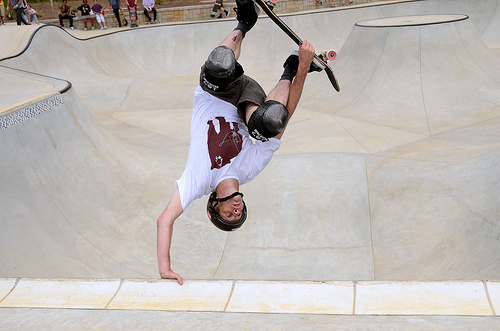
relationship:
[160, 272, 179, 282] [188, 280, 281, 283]
hand grabbing curb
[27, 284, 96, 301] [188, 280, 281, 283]
concrete tile in curb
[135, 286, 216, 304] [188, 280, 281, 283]
concrete tile in curb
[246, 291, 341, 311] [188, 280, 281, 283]
concrete tile in curb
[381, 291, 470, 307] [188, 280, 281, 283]
concrete tile on curb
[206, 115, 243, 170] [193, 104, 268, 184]
bear on shirt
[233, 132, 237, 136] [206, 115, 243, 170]
muzzle on bear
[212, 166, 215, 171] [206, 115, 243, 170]
ear on bear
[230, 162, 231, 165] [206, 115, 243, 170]
ear on bear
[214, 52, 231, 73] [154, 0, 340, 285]
kneepad on skateboarder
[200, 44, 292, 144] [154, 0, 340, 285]
kneepads on skateboarder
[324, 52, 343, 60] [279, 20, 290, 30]
wheel on skateboard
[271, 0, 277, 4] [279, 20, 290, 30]
wheel on skateboard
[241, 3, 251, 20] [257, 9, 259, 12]
sneaker on rubber sole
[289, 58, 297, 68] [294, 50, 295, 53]
sneaker on rubber sole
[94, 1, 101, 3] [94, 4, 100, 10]
person wearing shirt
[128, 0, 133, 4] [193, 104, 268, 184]
person wearing shirt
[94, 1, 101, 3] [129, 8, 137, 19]
person with skateboard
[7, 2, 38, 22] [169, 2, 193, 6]
people in background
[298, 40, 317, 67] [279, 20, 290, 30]
hand on skateboard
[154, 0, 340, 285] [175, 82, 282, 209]
skateboarder wearing shirt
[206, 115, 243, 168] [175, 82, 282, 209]
bear on shirt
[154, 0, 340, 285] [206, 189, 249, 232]
skateboarder wearing helmet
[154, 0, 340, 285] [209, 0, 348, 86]
skateboarder tricking on skateboard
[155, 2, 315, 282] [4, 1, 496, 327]
boy skating at skate park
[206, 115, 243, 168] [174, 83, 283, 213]
bear on shirt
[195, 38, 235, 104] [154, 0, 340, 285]
pad on skateboarder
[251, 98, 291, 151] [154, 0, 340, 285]
pad on skateboarder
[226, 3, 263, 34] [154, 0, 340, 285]
shoe on skateboarder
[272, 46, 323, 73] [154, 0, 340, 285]
shoe on skateboarder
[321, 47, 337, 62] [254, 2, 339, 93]
wheels on skateboard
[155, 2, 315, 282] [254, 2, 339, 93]
boy using skateboard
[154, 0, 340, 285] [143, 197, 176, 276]
skateboarder using arm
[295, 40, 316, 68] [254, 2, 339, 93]
hand holding skateboard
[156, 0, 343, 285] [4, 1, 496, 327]
skateboarder doing tricks at skate park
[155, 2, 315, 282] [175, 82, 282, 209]
boy wearing shirt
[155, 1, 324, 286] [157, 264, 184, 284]
boy has hand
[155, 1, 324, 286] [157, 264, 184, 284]
boy supporting himself on hand